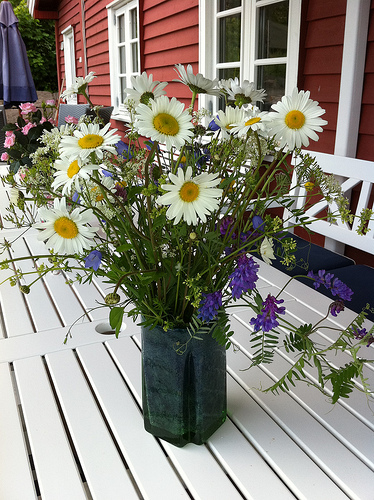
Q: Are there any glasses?
A: No, there are no glasses.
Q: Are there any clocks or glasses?
A: No, there are no glasses or clocks.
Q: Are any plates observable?
A: No, there are no plates.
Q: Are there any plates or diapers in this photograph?
A: No, there are no plates or diapers.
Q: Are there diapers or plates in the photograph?
A: No, there are no plates or diapers.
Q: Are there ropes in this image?
A: No, there are no ropes.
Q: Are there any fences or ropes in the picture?
A: No, there are no ropes or fences.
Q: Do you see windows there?
A: Yes, there is a window.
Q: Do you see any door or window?
A: Yes, there is a window.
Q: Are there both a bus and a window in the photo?
A: No, there is a window but no buses.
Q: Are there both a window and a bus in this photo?
A: No, there is a window but no buses.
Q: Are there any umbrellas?
A: Yes, there is an umbrella.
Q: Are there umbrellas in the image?
A: Yes, there is an umbrella.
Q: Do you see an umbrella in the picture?
A: Yes, there is an umbrella.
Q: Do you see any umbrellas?
A: Yes, there is an umbrella.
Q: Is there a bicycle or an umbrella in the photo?
A: Yes, there is an umbrella.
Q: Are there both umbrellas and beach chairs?
A: No, there is an umbrella but no beach chairs.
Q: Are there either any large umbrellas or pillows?
A: Yes, there is a large umbrella.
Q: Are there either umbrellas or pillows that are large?
A: Yes, the umbrella is large.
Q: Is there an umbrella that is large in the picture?
A: Yes, there is a large umbrella.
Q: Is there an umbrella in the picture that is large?
A: Yes, there is an umbrella that is large.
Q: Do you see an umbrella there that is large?
A: Yes, there is an umbrella that is large.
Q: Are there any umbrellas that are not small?
A: Yes, there is a large umbrella.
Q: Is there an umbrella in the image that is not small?
A: Yes, there is a large umbrella.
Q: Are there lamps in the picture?
A: No, there are no lamps.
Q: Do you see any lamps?
A: No, there are no lamps.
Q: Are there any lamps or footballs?
A: No, there are no lamps or footballs.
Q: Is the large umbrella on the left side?
A: Yes, the umbrella is on the left of the image.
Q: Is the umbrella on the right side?
A: No, the umbrella is on the left of the image.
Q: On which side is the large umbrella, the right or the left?
A: The umbrella is on the left of the image.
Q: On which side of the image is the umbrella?
A: The umbrella is on the left of the image.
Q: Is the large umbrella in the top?
A: Yes, the umbrella is in the top of the image.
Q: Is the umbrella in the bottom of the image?
A: No, the umbrella is in the top of the image.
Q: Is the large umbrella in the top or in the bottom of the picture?
A: The umbrella is in the top of the image.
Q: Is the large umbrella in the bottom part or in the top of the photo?
A: The umbrella is in the top of the image.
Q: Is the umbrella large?
A: Yes, the umbrella is large.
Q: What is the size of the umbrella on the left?
A: The umbrella is large.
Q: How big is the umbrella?
A: The umbrella is large.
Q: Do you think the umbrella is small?
A: No, the umbrella is large.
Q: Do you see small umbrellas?
A: No, there is an umbrella but it is large.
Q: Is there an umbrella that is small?
A: No, there is an umbrella but it is large.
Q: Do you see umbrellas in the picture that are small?
A: No, there is an umbrella but it is large.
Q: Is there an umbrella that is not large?
A: No, there is an umbrella but it is large.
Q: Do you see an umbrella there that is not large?
A: No, there is an umbrella but it is large.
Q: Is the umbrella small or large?
A: The umbrella is large.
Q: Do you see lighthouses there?
A: No, there are no lighthouses.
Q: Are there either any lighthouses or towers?
A: No, there are no lighthouses or towers.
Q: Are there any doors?
A: Yes, there is a door.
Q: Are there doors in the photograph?
A: Yes, there is a door.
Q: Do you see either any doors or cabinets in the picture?
A: Yes, there is a door.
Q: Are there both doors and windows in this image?
A: Yes, there are both a door and a window.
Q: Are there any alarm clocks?
A: No, there are no alarm clocks.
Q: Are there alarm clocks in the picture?
A: No, there are no alarm clocks.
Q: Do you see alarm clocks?
A: No, there are no alarm clocks.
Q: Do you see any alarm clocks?
A: No, there are no alarm clocks.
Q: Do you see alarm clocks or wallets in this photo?
A: No, there are no alarm clocks or wallets.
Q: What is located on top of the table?
A: The vase is on top of the table.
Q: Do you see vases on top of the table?
A: Yes, there is a vase on top of the table.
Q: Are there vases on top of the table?
A: Yes, there is a vase on top of the table.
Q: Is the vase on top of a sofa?
A: No, the vase is on top of the table.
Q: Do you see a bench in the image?
A: Yes, there is a bench.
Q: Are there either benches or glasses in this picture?
A: Yes, there is a bench.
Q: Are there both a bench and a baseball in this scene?
A: No, there is a bench but no baseballs.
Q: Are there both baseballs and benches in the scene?
A: No, there is a bench but no baseballs.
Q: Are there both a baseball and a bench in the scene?
A: No, there is a bench but no baseballs.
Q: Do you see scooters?
A: No, there are no scooters.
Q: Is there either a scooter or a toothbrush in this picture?
A: No, there are no scooters or toothbrushes.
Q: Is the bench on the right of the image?
A: Yes, the bench is on the right of the image.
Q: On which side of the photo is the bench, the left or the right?
A: The bench is on the right of the image.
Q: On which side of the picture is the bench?
A: The bench is on the right of the image.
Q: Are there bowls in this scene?
A: No, there are no bowls.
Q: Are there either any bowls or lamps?
A: No, there are no bowls or lamps.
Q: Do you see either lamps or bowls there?
A: No, there are no bowls or lamps.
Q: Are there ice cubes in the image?
A: No, there are no ice cubes.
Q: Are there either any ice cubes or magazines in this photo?
A: No, there are no ice cubes or magazines.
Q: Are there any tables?
A: Yes, there is a table.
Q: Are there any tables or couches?
A: Yes, there is a table.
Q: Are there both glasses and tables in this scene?
A: No, there is a table but no glasses.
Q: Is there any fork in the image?
A: No, there are no forks.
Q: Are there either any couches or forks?
A: No, there are no forks or couches.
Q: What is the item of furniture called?
A: The piece of furniture is a table.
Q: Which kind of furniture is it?
A: The piece of furniture is a table.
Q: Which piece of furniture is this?
A: This is a table.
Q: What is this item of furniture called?
A: This is a table.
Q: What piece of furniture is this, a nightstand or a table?
A: This is a table.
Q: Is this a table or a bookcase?
A: This is a table.